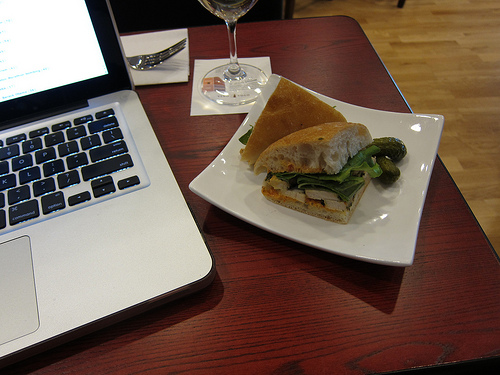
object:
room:
[0, 0, 500, 375]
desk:
[0, 11, 499, 375]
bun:
[248, 121, 374, 177]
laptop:
[0, 0, 216, 363]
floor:
[289, 0, 500, 258]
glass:
[194, 0, 270, 107]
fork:
[126, 38, 189, 72]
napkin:
[116, 26, 191, 89]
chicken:
[323, 197, 346, 211]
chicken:
[304, 188, 341, 202]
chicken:
[280, 188, 306, 203]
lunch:
[235, 76, 410, 224]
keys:
[117, 175, 141, 190]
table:
[0, 13, 500, 375]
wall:
[0, 15, 500, 375]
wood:
[0, 13, 500, 375]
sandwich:
[253, 120, 386, 226]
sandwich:
[236, 72, 345, 164]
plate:
[187, 73, 445, 267]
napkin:
[189, 55, 274, 118]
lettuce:
[265, 144, 384, 202]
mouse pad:
[0, 231, 43, 349]